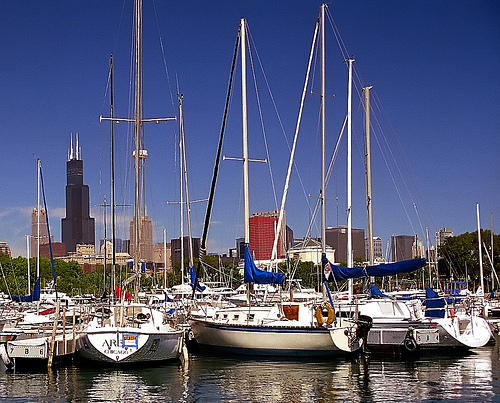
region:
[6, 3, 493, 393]
boats in a marina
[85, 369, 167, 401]
reflection of boat on water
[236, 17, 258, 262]
a white mast on a boat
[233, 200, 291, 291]
a sail near a boat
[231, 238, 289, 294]
sail is blue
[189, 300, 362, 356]
a white boat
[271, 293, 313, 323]
door of cabin of boat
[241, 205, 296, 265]
a red building in a city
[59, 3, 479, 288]
masts of yachts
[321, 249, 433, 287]
a big sail on yacht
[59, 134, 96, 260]
tall black building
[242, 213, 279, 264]
red building in the distance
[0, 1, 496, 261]
blue sky with few clouds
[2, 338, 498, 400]
calm reflective water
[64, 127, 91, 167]
antennas on top of building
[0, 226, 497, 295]
green trees in the background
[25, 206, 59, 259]
tall brown building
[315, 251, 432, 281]
blue sail cover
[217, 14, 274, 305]
white sailboat mast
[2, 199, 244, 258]
small white clouds against blue sky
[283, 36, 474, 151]
The sky is blue and clear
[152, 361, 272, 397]
The water is calm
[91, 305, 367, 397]
The boats are docked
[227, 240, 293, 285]
The flag is blue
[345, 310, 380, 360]
The motor is black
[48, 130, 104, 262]
The building is tall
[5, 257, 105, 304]
The leaves are green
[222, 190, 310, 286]
The building is in the back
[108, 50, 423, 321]
The boats have tall sails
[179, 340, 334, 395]
The water has reflections in it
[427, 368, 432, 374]
part of the ocean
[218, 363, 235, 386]
part of the sea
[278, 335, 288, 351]
side of a boat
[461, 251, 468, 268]
part of a tree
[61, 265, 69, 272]
part of a forest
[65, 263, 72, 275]
part of a forest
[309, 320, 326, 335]
edge of a boat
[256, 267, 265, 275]
part of a curtain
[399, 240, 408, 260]
edge of a building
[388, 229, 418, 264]
smaller brick building in the background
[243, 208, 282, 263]
red building in the background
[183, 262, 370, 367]
white boat in the water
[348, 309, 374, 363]
motor on a boat in the water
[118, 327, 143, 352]
for sale sign on boat in water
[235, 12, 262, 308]
pole on boat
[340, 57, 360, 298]
pole on boat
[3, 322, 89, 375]
brown and tan boat on the water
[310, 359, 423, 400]
ripples in the water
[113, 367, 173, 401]
ripples in the water